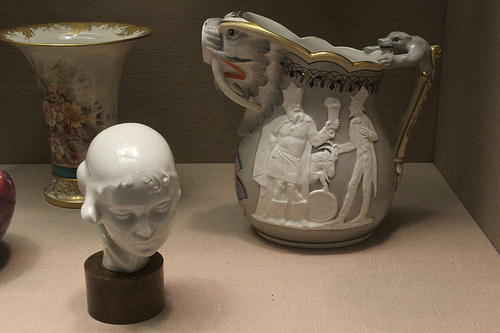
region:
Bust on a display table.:
[67, 90, 207, 287]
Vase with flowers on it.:
[13, 9, 157, 158]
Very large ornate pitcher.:
[192, 18, 466, 245]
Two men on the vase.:
[241, 73, 392, 233]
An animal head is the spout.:
[195, 12, 280, 105]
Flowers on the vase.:
[27, 68, 88, 184]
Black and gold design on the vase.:
[273, 63, 380, 94]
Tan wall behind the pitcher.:
[439, 19, 489, 170]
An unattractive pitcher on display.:
[199, 13, 443, 249]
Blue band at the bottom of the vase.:
[37, 156, 74, 192]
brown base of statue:
[77, 249, 174, 326]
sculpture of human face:
[60, 117, 182, 274]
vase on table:
[4, 15, 144, 212]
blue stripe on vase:
[49, 155, 79, 185]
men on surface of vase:
[250, 74, 382, 229]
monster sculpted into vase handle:
[362, 25, 433, 78]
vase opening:
[3, 14, 155, 59]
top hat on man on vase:
[344, 80, 376, 113]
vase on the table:
[202, 7, 421, 262]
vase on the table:
[22, 3, 91, 198]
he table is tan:
[195, 270, 302, 324]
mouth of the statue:
[130, 237, 166, 247]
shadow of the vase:
[181, 188, 259, 240]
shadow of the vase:
[415, 193, 452, 244]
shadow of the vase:
[22, 245, 47, 270]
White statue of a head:
[71, 121, 183, 273]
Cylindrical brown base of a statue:
[82, 247, 167, 326]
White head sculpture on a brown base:
[70, 121, 184, 324]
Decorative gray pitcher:
[199, 9, 444, 251]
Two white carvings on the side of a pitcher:
[249, 79, 376, 234]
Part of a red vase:
[0, 165, 16, 270]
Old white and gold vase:
[8, 20, 153, 210]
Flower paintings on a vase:
[23, 54, 114, 171]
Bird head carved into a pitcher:
[197, 5, 288, 136]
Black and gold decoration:
[277, 52, 385, 97]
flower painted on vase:
[39, 94, 60, 127]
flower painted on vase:
[49, 82, 70, 104]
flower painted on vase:
[62, 100, 84, 123]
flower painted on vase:
[49, 138, 67, 158]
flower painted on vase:
[62, 130, 81, 162]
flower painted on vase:
[53, 117, 72, 144]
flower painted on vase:
[90, 102, 112, 129]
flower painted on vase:
[32, 77, 51, 97]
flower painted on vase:
[54, 112, 74, 131]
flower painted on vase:
[98, 107, 119, 128]